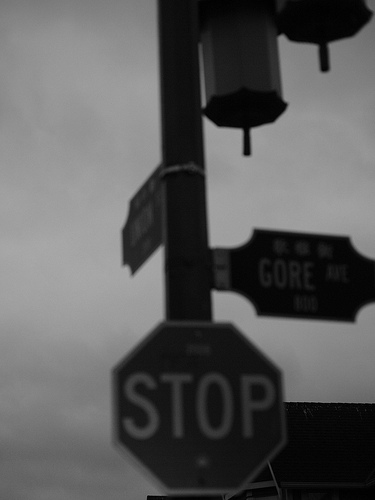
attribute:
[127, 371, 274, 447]
stop — white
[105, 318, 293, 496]
sign — octagonal, black, white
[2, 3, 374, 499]
sky — cloudy, grey, gray, white, gloomy, dreary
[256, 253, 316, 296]
gore — white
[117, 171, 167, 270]
road sign — perpendicular, decorative, angled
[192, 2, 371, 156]
lamps — hanging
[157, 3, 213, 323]
pole — large, black